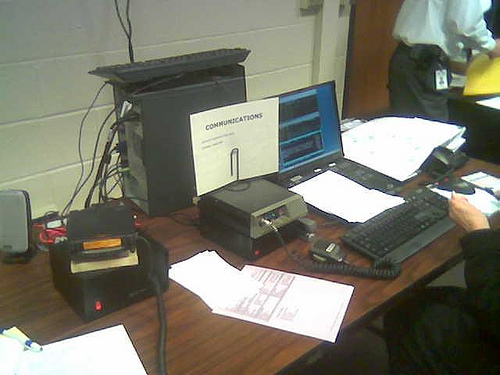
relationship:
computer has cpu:
[111, 63, 255, 217] [157, 121, 187, 142]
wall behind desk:
[1, 8, 364, 235] [2, 110, 497, 372]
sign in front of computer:
[184, 92, 284, 199] [111, 63, 255, 217]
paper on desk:
[209, 262, 361, 352] [2, 110, 497, 372]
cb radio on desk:
[197, 172, 312, 242] [2, 110, 497, 372]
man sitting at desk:
[376, 180, 500, 372] [2, 110, 497, 372]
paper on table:
[287, 166, 406, 237] [2, 110, 497, 372]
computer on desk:
[259, 78, 429, 225] [2, 110, 497, 372]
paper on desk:
[287, 166, 406, 237] [2, 110, 497, 372]